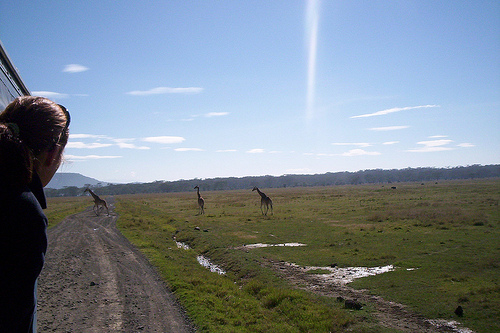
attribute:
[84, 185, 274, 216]
giraffes — walking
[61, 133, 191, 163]
clouds — white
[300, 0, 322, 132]
streak — white, thin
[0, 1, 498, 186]
sky — blue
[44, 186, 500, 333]
grass — short, wet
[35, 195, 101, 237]
grass — tall, brownish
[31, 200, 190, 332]
road — dirt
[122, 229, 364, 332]
ditch — grassy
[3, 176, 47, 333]
sweater — blue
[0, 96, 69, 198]
hair — brown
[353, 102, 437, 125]
cloud — white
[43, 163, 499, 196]
trees — lined